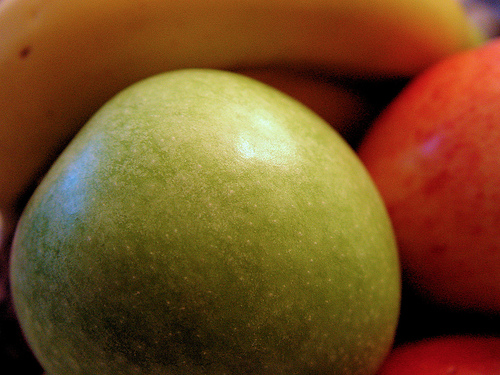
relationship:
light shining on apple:
[423, 135, 439, 155] [358, 35, 495, 215]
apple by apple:
[0, 52, 417, 374] [379, 300, 499, 365]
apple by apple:
[0, 52, 417, 374] [351, 42, 498, 332]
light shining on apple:
[423, 131, 439, 156] [354, 37, 499, 312]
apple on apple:
[8, 67, 401, 374] [354, 37, 499, 312]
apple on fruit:
[354, 37, 499, 312] [377, 326, 498, 371]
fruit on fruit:
[377, 326, 498, 371] [1, 0, 488, 201]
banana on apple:
[88, 21, 412, 61] [354, 37, 499, 312]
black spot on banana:
[17, 35, 39, 75] [4, 1, 449, 86]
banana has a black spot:
[0, 0, 487, 244] [17, 41, 35, 59]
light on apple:
[228, 112, 298, 170] [23, 61, 397, 373]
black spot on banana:
[17, 41, 35, 59] [0, 0, 487, 244]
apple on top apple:
[23, 61, 397, 373] [380, 331, 498, 368]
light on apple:
[144, 87, 373, 232] [23, 61, 397, 373]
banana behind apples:
[0, 0, 487, 244] [6, 62, 403, 373]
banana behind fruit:
[0, 0, 487, 244] [377, 335, 498, 374]